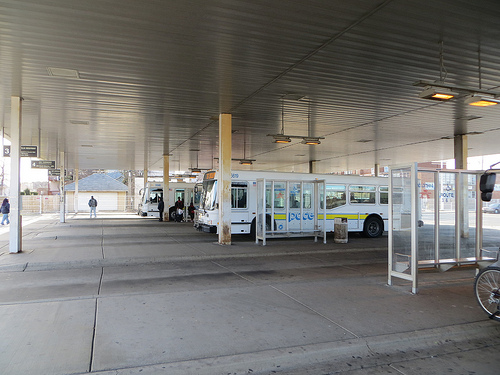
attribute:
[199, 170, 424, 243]
bus — white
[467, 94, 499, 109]
ceiling light — on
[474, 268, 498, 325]
wheel — in the picture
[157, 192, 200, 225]
people — in the picture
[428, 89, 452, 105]
light — on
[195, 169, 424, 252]
bus — white, stopped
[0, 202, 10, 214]
jacket — black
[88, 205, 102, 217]
pants — white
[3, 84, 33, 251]
pole — white, metal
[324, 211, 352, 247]
trash can — tan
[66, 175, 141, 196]
roof — gray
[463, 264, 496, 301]
tire — black, silver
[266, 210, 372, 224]
stripe — yellow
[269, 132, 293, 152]
light — yellow, square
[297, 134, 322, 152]
light — yellow, square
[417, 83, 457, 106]
light — yellow, square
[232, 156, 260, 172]
light — yellow, square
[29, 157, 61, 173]
sign — black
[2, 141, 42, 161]
sign — black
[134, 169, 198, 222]
bus — stopped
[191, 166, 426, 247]
bus — parked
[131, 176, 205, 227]
bus — parked